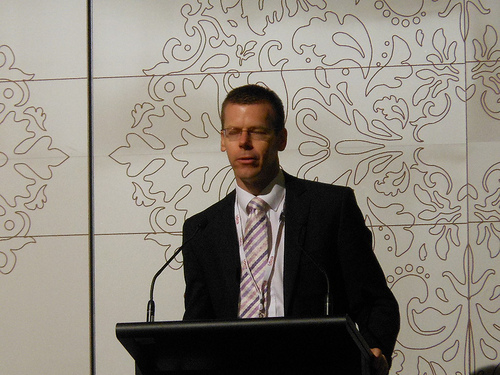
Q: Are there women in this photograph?
A: No, there are no women.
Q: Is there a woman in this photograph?
A: No, there are no women.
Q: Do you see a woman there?
A: No, there are no women.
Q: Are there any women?
A: No, there are no women.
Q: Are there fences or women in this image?
A: No, there are no women or fences.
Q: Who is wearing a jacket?
A: The man is wearing a jacket.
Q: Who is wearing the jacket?
A: The man is wearing a jacket.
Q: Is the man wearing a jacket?
A: Yes, the man is wearing a jacket.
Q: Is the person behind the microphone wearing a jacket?
A: Yes, the man is wearing a jacket.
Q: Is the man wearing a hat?
A: No, the man is wearing a jacket.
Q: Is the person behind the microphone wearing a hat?
A: No, the man is wearing a jacket.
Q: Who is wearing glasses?
A: The man is wearing glasses.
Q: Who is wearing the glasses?
A: The man is wearing glasses.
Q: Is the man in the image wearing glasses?
A: Yes, the man is wearing glasses.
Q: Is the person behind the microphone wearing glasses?
A: Yes, the man is wearing glasses.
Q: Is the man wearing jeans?
A: No, the man is wearing glasses.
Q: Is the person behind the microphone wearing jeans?
A: No, the man is wearing glasses.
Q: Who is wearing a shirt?
A: The man is wearing a shirt.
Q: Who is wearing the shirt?
A: The man is wearing a shirt.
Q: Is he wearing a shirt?
A: Yes, the man is wearing a shirt.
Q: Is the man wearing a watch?
A: No, the man is wearing a shirt.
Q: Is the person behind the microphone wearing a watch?
A: No, the man is wearing a shirt.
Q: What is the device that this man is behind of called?
A: The device is a microphone.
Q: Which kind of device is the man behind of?
A: The man is behind the microphone.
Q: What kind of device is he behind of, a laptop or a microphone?
A: The man is behind a microphone.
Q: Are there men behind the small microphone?
A: Yes, there is a man behind the microphone.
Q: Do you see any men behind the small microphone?
A: Yes, there is a man behind the microphone.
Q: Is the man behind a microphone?
A: Yes, the man is behind a microphone.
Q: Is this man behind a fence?
A: No, the man is behind a microphone.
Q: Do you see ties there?
A: Yes, there is a tie.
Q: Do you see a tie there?
A: Yes, there is a tie.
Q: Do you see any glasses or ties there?
A: Yes, there is a tie.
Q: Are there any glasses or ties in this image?
A: Yes, there is a tie.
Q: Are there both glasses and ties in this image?
A: Yes, there are both a tie and glasses.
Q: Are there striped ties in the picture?
A: Yes, there is a striped tie.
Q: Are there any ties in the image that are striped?
A: Yes, there is a tie that is striped.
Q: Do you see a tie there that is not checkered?
A: Yes, there is a striped tie.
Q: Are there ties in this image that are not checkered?
A: Yes, there is a striped tie.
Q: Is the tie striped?
A: Yes, the tie is striped.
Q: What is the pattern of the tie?
A: The necktie is striped.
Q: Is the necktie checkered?
A: No, the necktie is striped.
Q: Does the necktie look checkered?
A: No, the necktie is striped.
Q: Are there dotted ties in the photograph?
A: No, there is a tie but it is striped.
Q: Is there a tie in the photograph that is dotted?
A: No, there is a tie but it is striped.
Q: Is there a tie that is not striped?
A: No, there is a tie but it is striped.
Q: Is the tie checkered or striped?
A: The tie is striped.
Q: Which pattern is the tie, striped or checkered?
A: The tie is striped.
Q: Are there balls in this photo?
A: No, there are no balls.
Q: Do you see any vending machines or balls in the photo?
A: No, there are no balls or vending machines.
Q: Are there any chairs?
A: No, there are no chairs.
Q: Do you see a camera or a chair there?
A: No, there are no chairs or cameras.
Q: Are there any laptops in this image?
A: No, there are no laptops.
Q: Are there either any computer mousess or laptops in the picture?
A: No, there are no laptops or computer mousess.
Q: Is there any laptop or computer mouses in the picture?
A: No, there are no laptops or computer mousess.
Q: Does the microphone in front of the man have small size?
A: Yes, the microphone is small.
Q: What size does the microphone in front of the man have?
A: The microphone has small size.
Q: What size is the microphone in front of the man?
A: The microphone is small.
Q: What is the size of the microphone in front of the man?
A: The microphone is small.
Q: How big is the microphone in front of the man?
A: The microphone is small.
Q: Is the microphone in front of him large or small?
A: The microphone is small.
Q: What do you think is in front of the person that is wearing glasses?
A: The microphone is in front of the man.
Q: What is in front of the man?
A: The microphone is in front of the man.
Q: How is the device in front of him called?
A: The device is a microphone.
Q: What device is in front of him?
A: The device is a microphone.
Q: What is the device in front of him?
A: The device is a microphone.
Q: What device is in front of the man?
A: The device is a microphone.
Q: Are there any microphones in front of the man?
A: Yes, there is a microphone in front of the man.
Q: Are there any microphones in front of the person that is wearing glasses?
A: Yes, there is a microphone in front of the man.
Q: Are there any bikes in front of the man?
A: No, there is a microphone in front of the man.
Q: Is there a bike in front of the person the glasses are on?
A: No, there is a microphone in front of the man.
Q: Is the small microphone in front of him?
A: Yes, the microphone is in front of the man.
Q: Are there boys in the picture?
A: No, there are no boys.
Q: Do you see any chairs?
A: No, there are no chairs.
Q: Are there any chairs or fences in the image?
A: No, there are no chairs or fences.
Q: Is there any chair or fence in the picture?
A: No, there are no chairs or fences.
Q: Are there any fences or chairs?
A: No, there are no chairs or fences.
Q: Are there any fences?
A: No, there are no fences.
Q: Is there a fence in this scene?
A: No, there are no fences.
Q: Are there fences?
A: No, there are no fences.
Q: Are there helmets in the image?
A: No, there are no helmets.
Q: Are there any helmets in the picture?
A: No, there are no helmets.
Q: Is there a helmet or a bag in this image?
A: No, there are no helmets or bags.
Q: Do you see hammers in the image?
A: No, there are no hammers.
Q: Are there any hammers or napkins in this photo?
A: No, there are no hammers or napkins.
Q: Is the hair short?
A: Yes, the hair is short.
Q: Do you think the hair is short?
A: Yes, the hair is short.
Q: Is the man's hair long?
A: No, the hair is short.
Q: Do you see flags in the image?
A: No, there are no flags.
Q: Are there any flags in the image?
A: No, there are no flags.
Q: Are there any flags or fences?
A: No, there are no flags or fences.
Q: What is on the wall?
A: The art work is on the wall.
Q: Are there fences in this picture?
A: No, there are no fences.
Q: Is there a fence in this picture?
A: No, there are no fences.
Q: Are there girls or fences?
A: No, there are no fences or girls.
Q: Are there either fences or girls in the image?
A: No, there are no fences or girls.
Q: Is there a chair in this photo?
A: No, there are no chairs.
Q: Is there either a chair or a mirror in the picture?
A: No, there are no chairs or mirrors.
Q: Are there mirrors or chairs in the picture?
A: No, there are no chairs or mirrors.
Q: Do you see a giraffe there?
A: No, there are no giraffes.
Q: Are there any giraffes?
A: No, there are no giraffes.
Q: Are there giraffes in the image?
A: No, there are no giraffes.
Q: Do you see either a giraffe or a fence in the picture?
A: No, there are no giraffes or fences.